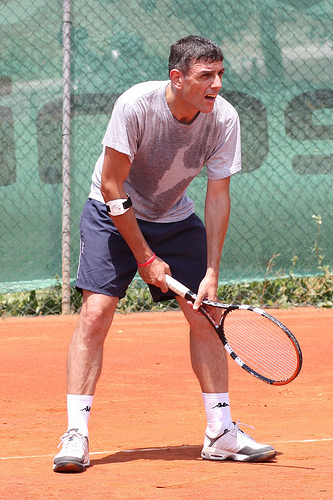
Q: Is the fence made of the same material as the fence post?
A: Yes, both the fence and the fence post are made of metal.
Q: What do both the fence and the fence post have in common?
A: The material, both the fence and the fence post are metallic.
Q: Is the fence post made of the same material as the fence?
A: Yes, both the fence post and the fence are made of metal.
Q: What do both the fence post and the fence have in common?
A: The material, both the fence post and the fence are metallic.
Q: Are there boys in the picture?
A: No, there are no boys.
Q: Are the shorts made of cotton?
A: Yes, the shorts are made of cotton.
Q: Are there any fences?
A: Yes, there is a fence.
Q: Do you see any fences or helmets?
A: Yes, there is a fence.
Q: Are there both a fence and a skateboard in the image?
A: No, there is a fence but no skateboards.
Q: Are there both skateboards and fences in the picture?
A: No, there is a fence but no skateboards.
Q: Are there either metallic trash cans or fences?
A: Yes, there is a metal fence.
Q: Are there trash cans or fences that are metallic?
A: Yes, the fence is metallic.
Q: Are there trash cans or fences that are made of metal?
A: Yes, the fence is made of metal.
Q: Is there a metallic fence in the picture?
A: Yes, there is a metal fence.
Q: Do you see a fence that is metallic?
A: Yes, there is a fence that is metallic.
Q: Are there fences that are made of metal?
A: Yes, there is a fence that is made of metal.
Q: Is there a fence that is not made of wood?
A: Yes, there is a fence that is made of metal.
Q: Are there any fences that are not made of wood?
A: Yes, there is a fence that is made of metal.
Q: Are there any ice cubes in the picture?
A: No, there are no ice cubes.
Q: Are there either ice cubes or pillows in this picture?
A: No, there are no ice cubes or pillows.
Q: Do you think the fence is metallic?
A: Yes, the fence is metallic.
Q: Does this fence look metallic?
A: Yes, the fence is metallic.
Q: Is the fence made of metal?
A: Yes, the fence is made of metal.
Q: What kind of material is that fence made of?
A: The fence is made of metal.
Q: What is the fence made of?
A: The fence is made of metal.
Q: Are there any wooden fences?
A: No, there is a fence but it is metallic.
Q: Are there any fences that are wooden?
A: No, there is a fence but it is metallic.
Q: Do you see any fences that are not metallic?
A: No, there is a fence but it is metallic.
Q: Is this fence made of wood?
A: No, the fence is made of metal.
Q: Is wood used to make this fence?
A: No, the fence is made of metal.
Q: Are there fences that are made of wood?
A: No, there is a fence but it is made of metal.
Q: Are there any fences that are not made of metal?
A: No, there is a fence but it is made of metal.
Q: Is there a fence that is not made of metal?
A: No, there is a fence but it is made of metal.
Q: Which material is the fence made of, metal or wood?
A: The fence is made of metal.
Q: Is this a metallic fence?
A: Yes, this is a metallic fence.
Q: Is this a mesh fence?
A: No, this is a metallic fence.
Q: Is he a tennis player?
A: Yes, this is a tennis player.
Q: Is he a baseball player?
A: No, this is a tennis player.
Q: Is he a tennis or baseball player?
A: This is a tennis player.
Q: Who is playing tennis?
A: The player is playing tennis.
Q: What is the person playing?
A: The player is playing tennis.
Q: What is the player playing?
A: The player is playing tennis.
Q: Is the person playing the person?
A: Yes, the player is playing tennis.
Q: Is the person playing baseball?
A: No, the player is playing tennis.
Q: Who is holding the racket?
A: The player is holding the racket.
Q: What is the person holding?
A: The player is holding the racket.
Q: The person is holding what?
A: The player is holding the racket.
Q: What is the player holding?
A: The player is holding the racket.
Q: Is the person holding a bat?
A: No, the player is holding the racket.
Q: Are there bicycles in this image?
A: No, there are no bicycles.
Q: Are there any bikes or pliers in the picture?
A: No, there are no bikes or pliers.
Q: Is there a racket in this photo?
A: Yes, there is a racket.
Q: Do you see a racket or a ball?
A: Yes, there is a racket.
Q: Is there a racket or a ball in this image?
A: Yes, there is a racket.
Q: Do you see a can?
A: No, there are no cans.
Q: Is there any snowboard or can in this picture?
A: No, there are no cans or snowboards.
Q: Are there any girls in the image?
A: No, there are no girls.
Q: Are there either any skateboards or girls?
A: No, there are no girls or skateboards.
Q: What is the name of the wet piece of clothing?
A: The clothing item is a t-shirt.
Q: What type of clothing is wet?
A: The clothing is a t-shirt.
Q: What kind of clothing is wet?
A: The clothing is a t-shirt.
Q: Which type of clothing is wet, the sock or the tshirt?
A: The tshirt is wet.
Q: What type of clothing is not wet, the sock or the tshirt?
A: The sock is not wet.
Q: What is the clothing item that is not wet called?
A: The clothing item is a sock.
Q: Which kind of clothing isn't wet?
A: The clothing is a sock.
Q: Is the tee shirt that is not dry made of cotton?
A: Yes, the tee shirt is made of cotton.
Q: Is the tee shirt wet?
A: Yes, the tee shirt is wet.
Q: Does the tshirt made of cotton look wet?
A: Yes, the tee shirt is wet.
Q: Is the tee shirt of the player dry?
A: No, the tshirt is wet.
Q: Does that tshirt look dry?
A: No, the tshirt is wet.